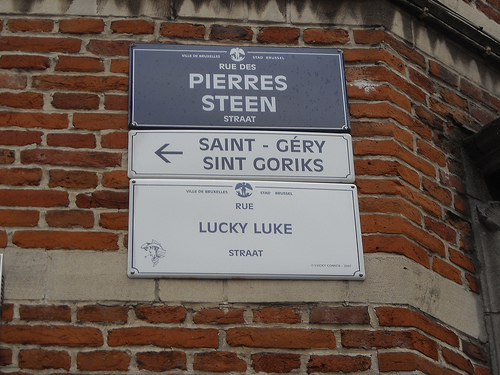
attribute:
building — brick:
[0, 0, 498, 373]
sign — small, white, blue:
[132, 37, 362, 135]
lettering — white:
[185, 70, 291, 115]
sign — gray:
[127, 40, 352, 134]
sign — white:
[126, 178, 366, 280]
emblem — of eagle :
[233, 180, 252, 199]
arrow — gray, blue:
[154, 142, 183, 163]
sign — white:
[123, 37, 381, 299]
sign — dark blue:
[139, 46, 390, 148]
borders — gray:
[129, 131, 367, 282]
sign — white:
[127, 127, 352, 182]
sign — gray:
[131, 45, 344, 132]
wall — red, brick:
[4, 20, 493, 371]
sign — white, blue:
[116, 50, 433, 167]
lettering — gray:
[127, 41, 351, 131]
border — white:
[126, 40, 352, 133]